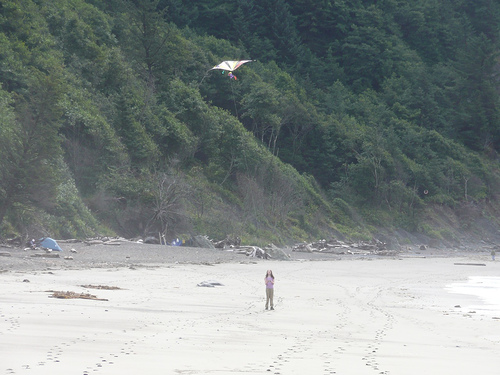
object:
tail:
[227, 69, 239, 82]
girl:
[262, 266, 277, 312]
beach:
[0, 239, 499, 373]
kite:
[198, 57, 258, 88]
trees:
[0, 54, 70, 221]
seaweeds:
[76, 282, 131, 294]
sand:
[110, 289, 223, 348]